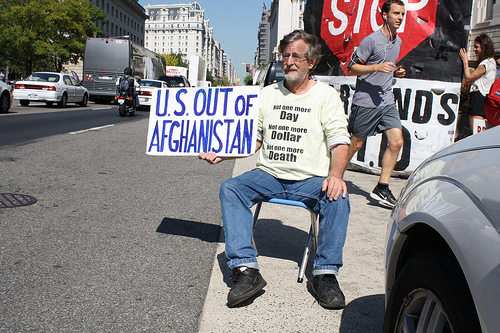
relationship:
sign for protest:
[144, 86, 259, 157] [146, 4, 499, 160]